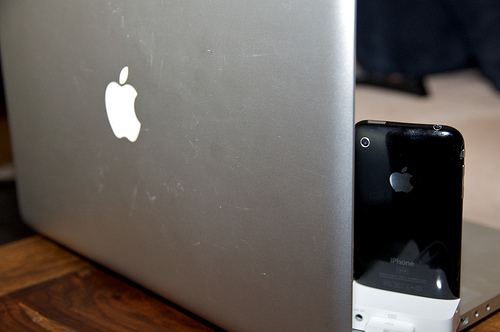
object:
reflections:
[351, 124, 464, 298]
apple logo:
[104, 66, 140, 143]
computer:
[1, 1, 498, 330]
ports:
[461, 304, 491, 327]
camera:
[359, 136, 371, 148]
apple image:
[389, 167, 414, 193]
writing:
[390, 256, 415, 267]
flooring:
[351, 70, 498, 221]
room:
[2, 1, 499, 328]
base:
[348, 218, 498, 332]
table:
[1, 236, 497, 332]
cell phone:
[353, 118, 467, 300]